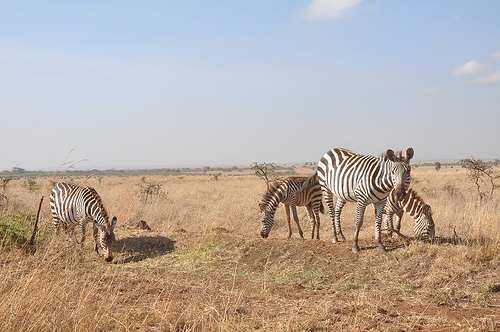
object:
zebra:
[49, 182, 122, 260]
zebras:
[255, 148, 435, 253]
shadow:
[102, 235, 175, 265]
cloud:
[443, 57, 500, 88]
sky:
[0, 1, 500, 173]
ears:
[91, 217, 119, 235]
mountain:
[0, 162, 34, 176]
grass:
[0, 246, 270, 331]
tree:
[252, 156, 295, 194]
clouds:
[302, 1, 500, 98]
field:
[0, 186, 500, 331]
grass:
[0, 199, 50, 257]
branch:
[29, 195, 47, 246]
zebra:
[317, 147, 415, 252]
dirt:
[102, 273, 201, 331]